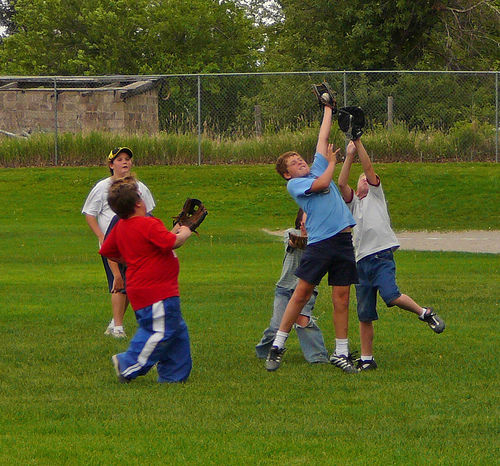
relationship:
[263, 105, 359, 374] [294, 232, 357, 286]
boy wearing shorts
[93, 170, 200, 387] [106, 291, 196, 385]
boy wearing pants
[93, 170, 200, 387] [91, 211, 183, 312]
boy wearing t-shirt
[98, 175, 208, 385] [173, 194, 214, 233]
boy wearing baseball glove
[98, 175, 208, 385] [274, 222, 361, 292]
boy wearing shorts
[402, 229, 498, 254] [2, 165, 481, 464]
gravel on field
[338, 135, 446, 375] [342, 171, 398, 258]
boy wearing shirt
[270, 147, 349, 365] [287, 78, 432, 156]
boy catching baseball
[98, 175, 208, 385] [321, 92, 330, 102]
boy catching ball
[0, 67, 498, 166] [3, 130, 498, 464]
fence along grass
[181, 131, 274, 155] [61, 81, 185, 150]
grass behind fence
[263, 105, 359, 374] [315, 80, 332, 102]
boy catching ball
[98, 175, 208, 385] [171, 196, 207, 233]
boy wearing baseball glove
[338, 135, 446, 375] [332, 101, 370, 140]
boy wearing glove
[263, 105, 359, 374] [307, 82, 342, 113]
boy catching a ball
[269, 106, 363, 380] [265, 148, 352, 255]
boy wearing a shirt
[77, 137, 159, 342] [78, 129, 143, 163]
boy wearing a hat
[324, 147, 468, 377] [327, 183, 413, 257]
boy wearing a shirt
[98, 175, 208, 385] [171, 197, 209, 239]
boy wearing a baseball glove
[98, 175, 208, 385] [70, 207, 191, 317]
boy wearing a shirt